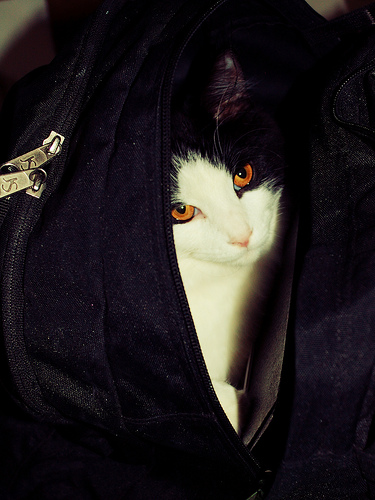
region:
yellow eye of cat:
[169, 198, 197, 225]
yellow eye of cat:
[233, 161, 256, 191]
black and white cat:
[160, 74, 281, 437]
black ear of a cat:
[207, 55, 257, 117]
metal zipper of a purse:
[3, 129, 64, 206]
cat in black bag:
[16, 5, 313, 491]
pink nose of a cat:
[222, 224, 253, 254]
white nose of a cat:
[174, 149, 253, 235]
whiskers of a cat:
[253, 192, 283, 243]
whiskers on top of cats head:
[204, 106, 236, 170]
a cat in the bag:
[160, 145, 301, 376]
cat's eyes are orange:
[145, 157, 265, 240]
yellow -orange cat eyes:
[169, 155, 264, 230]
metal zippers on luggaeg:
[1, 126, 71, 211]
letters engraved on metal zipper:
[0, 174, 23, 194]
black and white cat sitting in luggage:
[168, 48, 305, 477]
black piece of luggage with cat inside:
[1, 17, 368, 495]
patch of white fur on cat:
[197, 283, 249, 326]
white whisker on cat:
[203, 85, 234, 165]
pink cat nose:
[220, 228, 266, 254]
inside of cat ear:
[205, 48, 262, 140]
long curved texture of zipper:
[0, 199, 57, 410]